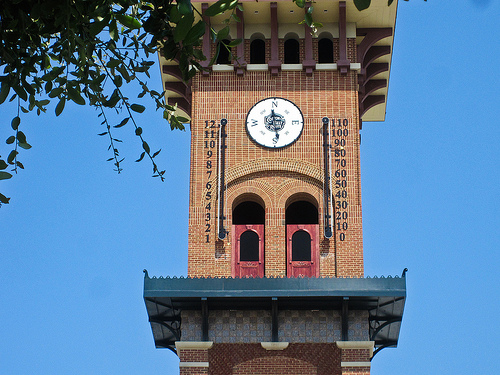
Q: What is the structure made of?
A: Brick.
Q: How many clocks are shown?
A: One.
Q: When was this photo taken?
A: Day time.